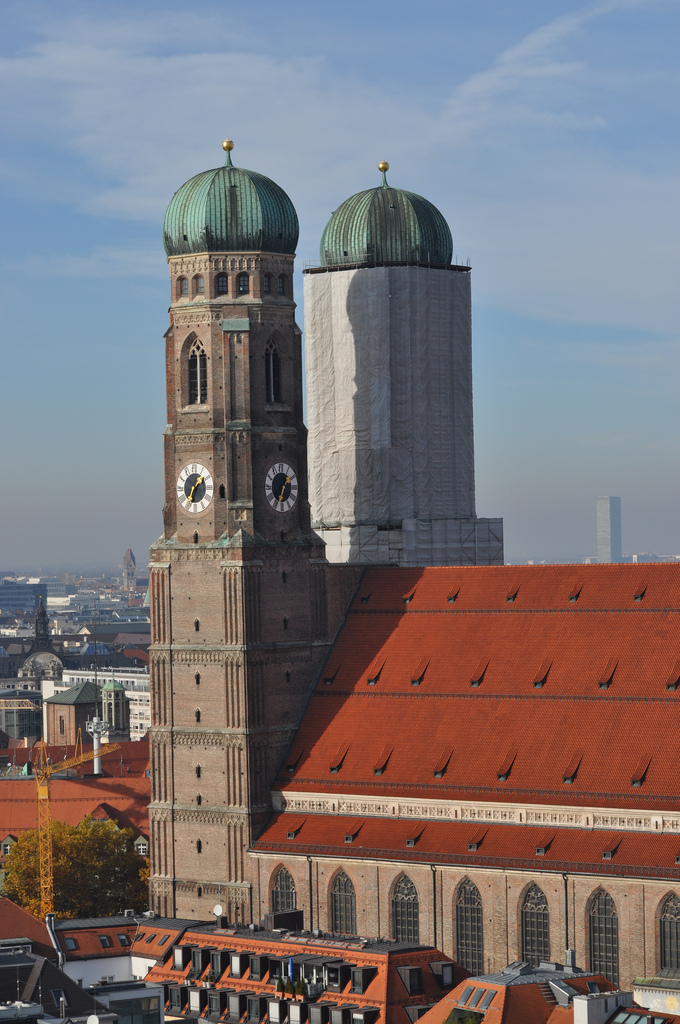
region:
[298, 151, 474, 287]
the dome is green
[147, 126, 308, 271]
the dome is green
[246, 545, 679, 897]
the roof is read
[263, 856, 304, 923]
a window on a church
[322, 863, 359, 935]
a window on a church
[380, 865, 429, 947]
a window on a church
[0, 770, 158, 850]
the roof is red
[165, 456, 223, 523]
a clock on a tower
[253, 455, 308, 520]
a clock on a tower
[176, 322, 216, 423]
a window below the dome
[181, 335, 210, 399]
a window on a building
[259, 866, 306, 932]
a window on a building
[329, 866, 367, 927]
a window on a building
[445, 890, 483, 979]
a window on a building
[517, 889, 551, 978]
a window on a building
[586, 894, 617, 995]
a window on a building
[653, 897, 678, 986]
a window on a building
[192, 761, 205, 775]
a window on a building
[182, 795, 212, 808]
a window on a building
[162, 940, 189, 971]
window on the building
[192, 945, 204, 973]
window on the building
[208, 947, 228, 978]
window on the building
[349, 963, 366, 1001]
window on the building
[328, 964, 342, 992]
window on the building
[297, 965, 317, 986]
window on the building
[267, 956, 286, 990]
window on the building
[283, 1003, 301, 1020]
window on the building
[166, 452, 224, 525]
Clock on a tower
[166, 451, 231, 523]
Clock is on a tower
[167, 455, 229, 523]
Clock on a building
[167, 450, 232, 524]
Clock is on a building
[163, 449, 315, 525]
Clocks on a tower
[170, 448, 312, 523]
Clocks are on a tower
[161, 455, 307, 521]
Clocks on a building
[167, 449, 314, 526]
Clocks are on a building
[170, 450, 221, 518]
Clock on the side of a building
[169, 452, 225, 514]
Clock is on the side of a building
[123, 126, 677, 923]
large church with dome and clock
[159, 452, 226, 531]
clock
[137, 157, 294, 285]
green dome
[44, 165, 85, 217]
white clouds in blue sky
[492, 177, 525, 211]
white clouds in blue sky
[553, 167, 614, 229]
white clouds in blue sky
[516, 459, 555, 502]
white clouds in blue sky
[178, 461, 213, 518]
a clock on the building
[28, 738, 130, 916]
a large yellow crane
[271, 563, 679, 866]
the red roof of the building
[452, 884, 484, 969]
the window on the building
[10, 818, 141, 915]
trees next to the building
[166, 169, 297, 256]
the green roof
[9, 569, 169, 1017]
many tall buildings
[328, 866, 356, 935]
A window on a building.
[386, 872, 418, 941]
A window on a building.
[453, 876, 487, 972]
A window on a building.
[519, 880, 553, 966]
A window on a building.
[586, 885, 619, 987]
A window on a building.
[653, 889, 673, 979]
A window on a building.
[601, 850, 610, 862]
A window on a building.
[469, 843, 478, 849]
A window on a building.